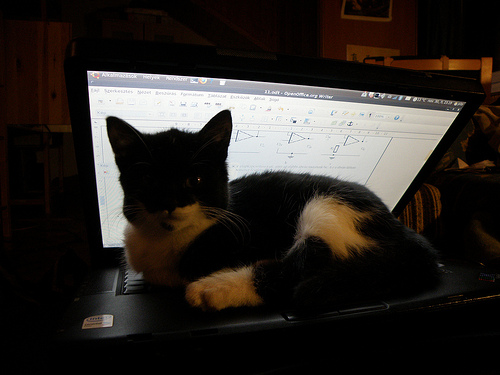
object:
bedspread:
[392, 184, 442, 236]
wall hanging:
[340, 0, 394, 22]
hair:
[209, 168, 426, 299]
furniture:
[365, 56, 493, 93]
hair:
[157, 134, 203, 162]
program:
[87, 70, 468, 249]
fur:
[104, 110, 437, 309]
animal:
[104, 108, 444, 312]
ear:
[194, 108, 233, 162]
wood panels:
[0, 0, 73, 214]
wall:
[0, 0, 499, 136]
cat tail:
[291, 217, 440, 313]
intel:
[84, 71, 467, 249]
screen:
[86, 71, 466, 248]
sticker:
[82, 314, 114, 330]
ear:
[104, 115, 151, 173]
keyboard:
[120, 273, 186, 294]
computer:
[54, 37, 500, 343]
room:
[0, 0, 500, 375]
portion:
[413, 194, 433, 224]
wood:
[363, 55, 493, 93]